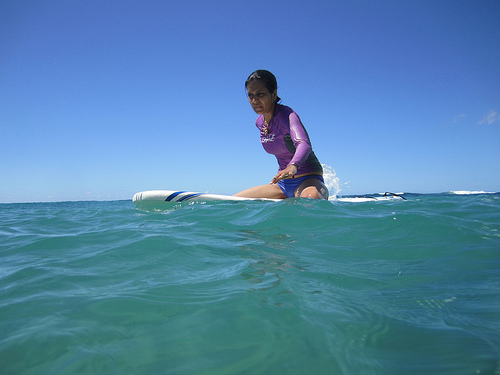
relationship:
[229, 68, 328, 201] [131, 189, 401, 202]
woman sitting on surfboard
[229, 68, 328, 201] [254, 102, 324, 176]
woman wearing top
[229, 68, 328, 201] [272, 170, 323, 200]
woman wearing bikini bottoms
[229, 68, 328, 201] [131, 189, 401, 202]
woman using surfboard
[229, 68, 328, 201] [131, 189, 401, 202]
woman riding surfboard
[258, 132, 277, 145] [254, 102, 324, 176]
writing on chest of top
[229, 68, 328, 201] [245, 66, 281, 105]
woman has hair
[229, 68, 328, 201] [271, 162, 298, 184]
woman has hand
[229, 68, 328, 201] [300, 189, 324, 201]
woman has knee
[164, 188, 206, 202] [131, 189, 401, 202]
stripes printed on surfboard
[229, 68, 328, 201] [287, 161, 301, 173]
woman wearing wrist watch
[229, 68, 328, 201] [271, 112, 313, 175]
woman has arm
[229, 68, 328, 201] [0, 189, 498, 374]
woman in ocean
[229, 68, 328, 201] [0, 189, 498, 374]
woman floating on ocean